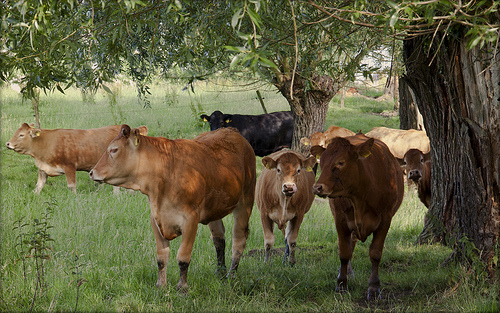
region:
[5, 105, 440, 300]
Cows on the grass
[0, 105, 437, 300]
Cows are on the grass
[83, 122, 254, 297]
Brown cow on the grass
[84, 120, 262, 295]
Brown cow is on the grass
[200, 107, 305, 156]
Black cow on the grass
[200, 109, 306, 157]
Black cow is on the grass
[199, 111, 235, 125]
Cow tagged on ears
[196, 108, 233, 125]
Cow has tags on both ears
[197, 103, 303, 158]
Black cow behind a tree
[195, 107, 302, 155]
Black cow is behind a tree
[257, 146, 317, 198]
Face of a brown cowl looking straight forward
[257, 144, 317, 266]
Brown cow facing front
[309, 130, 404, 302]
Brown cow showing the left half of her face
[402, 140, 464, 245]
A brown cow peeking around a tree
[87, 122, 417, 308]
A grouping of brown cows standing in grass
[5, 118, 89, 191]
The left front half of a brown cow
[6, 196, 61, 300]
Tall weeds in green grass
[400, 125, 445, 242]
A brown calf peekig around a tree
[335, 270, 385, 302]
Front hooves of a brown cow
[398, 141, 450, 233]
A cow peeking out behind a tree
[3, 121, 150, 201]
A brown cow in the background.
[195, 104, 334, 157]
A black cow behind a tree.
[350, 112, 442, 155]
A tan cow in the background.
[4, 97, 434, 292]
Eight cows in the pasture.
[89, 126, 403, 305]
Three cows in the front of the picture.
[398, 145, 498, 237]
Brown cow behind a tree.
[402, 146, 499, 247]
Brown cow sticking his head out from behind the tree.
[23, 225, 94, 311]
The grass in the pasture.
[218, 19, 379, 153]
A tree that the cows are around.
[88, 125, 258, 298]
A brown cow in the front of the photograph.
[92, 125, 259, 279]
a stocky orange cow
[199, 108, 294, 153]
a black cow in the back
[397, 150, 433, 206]
an inquisitive cow head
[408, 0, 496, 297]
a thick tree trunk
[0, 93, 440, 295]
a herd of orange and black cattle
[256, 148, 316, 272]
a cow with a white belly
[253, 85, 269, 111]
a toppled fence post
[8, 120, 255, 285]
two cows facing outwards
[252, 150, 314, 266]
a cow facing forwards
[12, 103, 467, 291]
a herd of cattle in a field